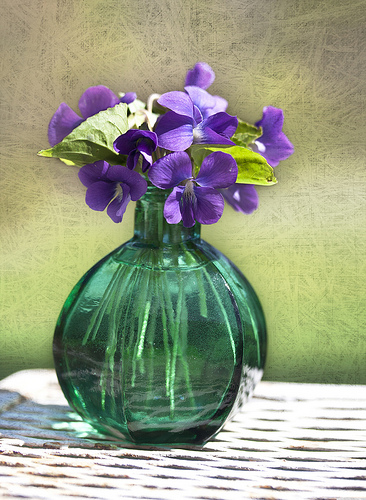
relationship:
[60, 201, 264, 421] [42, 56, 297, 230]
stems of flowers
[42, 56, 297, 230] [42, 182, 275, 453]
flowers in vase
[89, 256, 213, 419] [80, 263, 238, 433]
stems in water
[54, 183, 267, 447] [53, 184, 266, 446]
vase with glass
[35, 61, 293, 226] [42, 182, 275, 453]
rose petals in vase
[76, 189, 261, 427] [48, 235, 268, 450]
green stems in water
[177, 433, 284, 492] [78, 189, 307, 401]
grate under vase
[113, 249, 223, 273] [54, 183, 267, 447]
water line in vase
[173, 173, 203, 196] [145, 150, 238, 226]
center of a flower